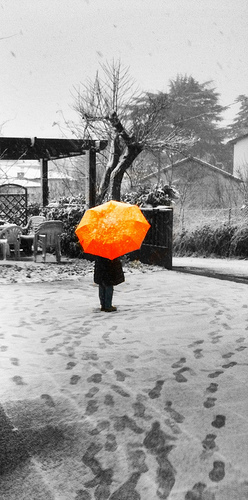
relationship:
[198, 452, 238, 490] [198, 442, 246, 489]
footprint in snow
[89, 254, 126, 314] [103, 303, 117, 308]
person wearing boots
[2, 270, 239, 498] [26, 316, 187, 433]
snow on ground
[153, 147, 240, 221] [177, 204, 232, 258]
building behind fence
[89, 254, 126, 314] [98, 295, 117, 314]
person wearing boots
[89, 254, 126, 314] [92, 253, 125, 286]
person wearing coat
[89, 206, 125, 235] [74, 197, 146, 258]
snow on top of umbrella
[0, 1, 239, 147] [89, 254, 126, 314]
sky above person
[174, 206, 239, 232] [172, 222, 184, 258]
fence by bushes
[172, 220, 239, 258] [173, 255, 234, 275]
bushes above snow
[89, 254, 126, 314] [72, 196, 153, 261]
person beneath umbrella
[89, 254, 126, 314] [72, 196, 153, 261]
person holding umbrella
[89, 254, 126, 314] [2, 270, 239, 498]
person in snow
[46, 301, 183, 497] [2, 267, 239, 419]
footprints in snow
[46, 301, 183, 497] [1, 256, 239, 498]
footprints on ground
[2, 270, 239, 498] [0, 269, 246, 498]
snow on pavement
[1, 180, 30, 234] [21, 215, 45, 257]
trellis behind chair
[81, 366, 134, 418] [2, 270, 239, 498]
footprints in snow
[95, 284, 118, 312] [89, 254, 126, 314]
legs of person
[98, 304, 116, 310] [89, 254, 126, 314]
feet of person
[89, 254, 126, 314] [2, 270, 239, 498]
person standing in snow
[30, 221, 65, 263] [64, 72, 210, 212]
chair near tree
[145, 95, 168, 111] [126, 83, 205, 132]
leaves on bush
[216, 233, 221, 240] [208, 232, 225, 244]
leaves on bush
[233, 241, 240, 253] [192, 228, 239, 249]
leaves on bush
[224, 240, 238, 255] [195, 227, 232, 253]
leaves on bush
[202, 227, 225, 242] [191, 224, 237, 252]
leaves on bush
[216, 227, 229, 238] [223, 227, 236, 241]
leaves on bush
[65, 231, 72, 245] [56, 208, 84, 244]
leaves on bush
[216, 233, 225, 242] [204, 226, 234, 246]
leaves on bush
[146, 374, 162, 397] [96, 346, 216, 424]
footprint in snow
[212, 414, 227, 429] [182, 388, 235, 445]
footprint in snow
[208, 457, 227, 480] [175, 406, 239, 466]
footprint in snow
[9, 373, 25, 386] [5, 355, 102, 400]
footprint in snow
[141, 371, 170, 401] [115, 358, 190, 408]
footprint in snow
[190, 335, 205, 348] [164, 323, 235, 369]
footprint in snow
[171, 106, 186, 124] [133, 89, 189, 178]
leaves on tree